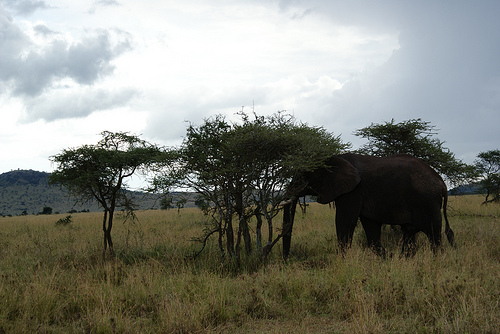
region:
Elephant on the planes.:
[286, 137, 493, 214]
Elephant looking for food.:
[278, 127, 353, 327]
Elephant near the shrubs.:
[212, 95, 394, 296]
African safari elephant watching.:
[182, 78, 486, 245]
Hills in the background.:
[23, 144, 222, 296]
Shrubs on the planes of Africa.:
[208, 116, 375, 253]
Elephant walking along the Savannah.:
[278, 112, 494, 264]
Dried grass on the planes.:
[246, 100, 469, 311]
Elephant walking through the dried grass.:
[240, 111, 499, 320]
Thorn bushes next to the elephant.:
[221, 110, 377, 297]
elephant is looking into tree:
[281, 154, 456, 259]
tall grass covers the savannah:
[0, 192, 499, 332]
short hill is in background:
[0, 167, 316, 216]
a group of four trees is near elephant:
[48, 100, 499, 270]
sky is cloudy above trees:
[0, 0, 499, 193]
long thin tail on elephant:
[442, 182, 454, 244]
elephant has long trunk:
[281, 172, 314, 265]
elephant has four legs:
[335, 193, 443, 258]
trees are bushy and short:
[48, 97, 498, 268]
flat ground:
[0, 193, 499, 332]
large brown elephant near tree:
[279, 147, 456, 259]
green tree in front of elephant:
[151, 100, 348, 272]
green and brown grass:
[1, 187, 498, 331]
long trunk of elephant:
[280, 185, 300, 263]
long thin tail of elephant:
[443, 185, 457, 247]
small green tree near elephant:
[47, 125, 180, 257]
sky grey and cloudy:
[1, 0, 498, 196]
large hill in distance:
[1, 167, 141, 214]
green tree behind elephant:
[351, 117, 485, 187]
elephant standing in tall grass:
[281, 145, 458, 260]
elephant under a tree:
[268, 140, 466, 262]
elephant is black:
[271, 138, 461, 259]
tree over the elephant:
[143, 98, 358, 268]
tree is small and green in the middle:
[156, 102, 351, 273]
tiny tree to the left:
[42, 130, 182, 260]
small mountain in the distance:
[1, 162, 320, 218]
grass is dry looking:
[0, 194, 499, 330]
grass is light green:
[1, 191, 499, 332]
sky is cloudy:
[1, 1, 498, 189]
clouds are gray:
[1, 1, 134, 128]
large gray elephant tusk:
[275, 187, 307, 239]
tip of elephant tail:
[446, 222, 461, 248]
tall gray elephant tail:
[429, 170, 471, 264]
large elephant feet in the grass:
[323, 204, 387, 259]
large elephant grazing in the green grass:
[261, 156, 465, 271]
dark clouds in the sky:
[392, 27, 471, 112]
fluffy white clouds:
[157, 19, 291, 84]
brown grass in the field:
[83, 277, 246, 317]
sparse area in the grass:
[226, 297, 311, 326]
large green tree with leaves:
[33, 112, 186, 272]